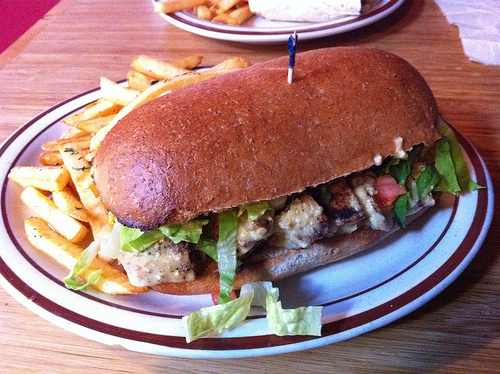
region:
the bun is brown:
[131, 120, 348, 170]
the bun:
[127, 131, 256, 189]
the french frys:
[23, 170, 78, 253]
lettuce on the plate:
[200, 305, 292, 323]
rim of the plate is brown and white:
[375, 295, 407, 312]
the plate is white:
[352, 259, 396, 283]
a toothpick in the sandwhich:
[282, 33, 302, 82]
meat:
[283, 206, 323, 243]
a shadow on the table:
[431, 308, 478, 348]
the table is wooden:
[8, 337, 60, 369]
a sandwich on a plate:
[6, 30, 488, 365]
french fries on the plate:
[33, 43, 234, 300]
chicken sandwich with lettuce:
[111, 40, 476, 290]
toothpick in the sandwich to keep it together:
[280, 15, 305, 85]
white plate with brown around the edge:
[0, 55, 480, 355]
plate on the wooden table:
[5, 0, 486, 362]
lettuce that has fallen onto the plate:
[163, 281, 338, 331]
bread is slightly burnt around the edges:
[93, 188, 191, 231]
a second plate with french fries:
[146, 0, 412, 42]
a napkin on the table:
[439, 0, 496, 75]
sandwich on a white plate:
[1, 21, 483, 372]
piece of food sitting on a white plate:
[172, 276, 337, 353]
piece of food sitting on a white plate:
[14, 213, 142, 305]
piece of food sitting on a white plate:
[15, 181, 91, 250]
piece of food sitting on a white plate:
[3, 161, 70, 193]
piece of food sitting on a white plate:
[51, 185, 93, 226]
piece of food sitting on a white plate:
[61, 142, 121, 260]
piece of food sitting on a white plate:
[124, 46, 182, 84]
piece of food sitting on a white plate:
[97, 71, 143, 106]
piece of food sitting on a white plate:
[74, 110, 113, 135]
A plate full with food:
[3, 42, 495, 364]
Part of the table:
[438, 343, 471, 368]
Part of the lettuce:
[209, 306, 244, 323]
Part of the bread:
[201, 113, 243, 150]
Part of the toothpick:
[283, 45, 301, 67]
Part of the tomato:
[381, 182, 395, 197]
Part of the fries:
[32, 171, 67, 203]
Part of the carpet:
[3, 8, 23, 22]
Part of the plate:
[363, 258, 382, 273]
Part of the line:
[346, 287, 356, 304]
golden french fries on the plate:
[10, 147, 106, 258]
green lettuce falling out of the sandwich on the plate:
[175, 277, 350, 370]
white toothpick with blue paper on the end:
[245, 30, 346, 105]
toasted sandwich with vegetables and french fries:
[31, 35, 426, 302]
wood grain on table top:
[15, 15, 116, 71]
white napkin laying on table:
[415, 5, 498, 75]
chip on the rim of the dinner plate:
[71, 325, 156, 368]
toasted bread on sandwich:
[82, 167, 213, 247]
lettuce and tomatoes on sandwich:
[332, 138, 486, 252]